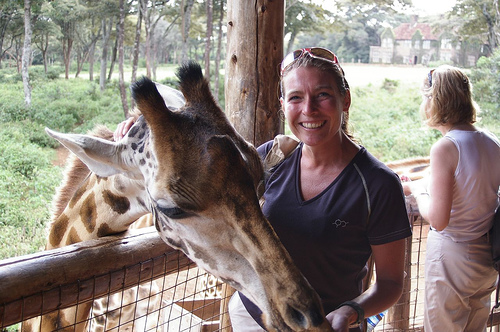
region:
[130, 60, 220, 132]
knobs on the head of a giraffe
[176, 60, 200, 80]
hair on the top of a knob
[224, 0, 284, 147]
a sturdy wooden post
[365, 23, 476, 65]
building in the distance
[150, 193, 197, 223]
right eye of a giraffe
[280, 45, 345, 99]
glasses on the head of a woman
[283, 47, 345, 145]
smiling face of a woman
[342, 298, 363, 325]
wrist watch on the arm of a woman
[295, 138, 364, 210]
V neck of a shirt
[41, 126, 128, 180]
left ear of the giraffe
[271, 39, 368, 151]
A woman's head with sunglasses on.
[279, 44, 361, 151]
A woman's head with small sunglasses on.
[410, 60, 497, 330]
A woman with a white shirt on.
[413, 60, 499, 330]
A woman with a white tanktop on.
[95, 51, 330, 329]
Head of a giraffe next to a woman.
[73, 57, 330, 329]
Big head of a giraffe next to a woman.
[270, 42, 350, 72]
Sunglasses on a woman's head.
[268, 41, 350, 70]
Red sunglasses on a woman's head.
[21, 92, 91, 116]
Bushes outside in the background.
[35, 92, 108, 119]
Green bushes outside in the background.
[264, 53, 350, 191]
the woman is smiling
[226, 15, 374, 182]
the woman is smiling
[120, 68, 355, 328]
giraffe feeding on woman's hand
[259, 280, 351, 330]
giraffe feeding on woman's hand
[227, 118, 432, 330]
giraffe feeding on woman's hand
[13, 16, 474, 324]
A giraffe in an enclosure.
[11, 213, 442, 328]
A wire fence.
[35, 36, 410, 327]
Woman petting a giraffe.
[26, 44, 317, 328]
Giraffe with head over a fence.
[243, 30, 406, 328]
Shirt with a v neckline.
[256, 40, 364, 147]
A pair of sunglasses.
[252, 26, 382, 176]
Woman has hair pulled back.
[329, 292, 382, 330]
Watch on woman's left wrist.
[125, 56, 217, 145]
Horns on giraffe's head.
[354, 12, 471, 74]
House in the background.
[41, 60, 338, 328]
the giraffe leaning over the fence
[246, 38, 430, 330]
the woman petting the giraffe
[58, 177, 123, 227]
the spots on the giraffe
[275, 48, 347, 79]
the sunglasses on the head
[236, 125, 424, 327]
the woman wearing a blue t shirt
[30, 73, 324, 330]
the head of the giraffe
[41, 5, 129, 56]
the trees with green leaves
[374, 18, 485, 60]
the house in the distance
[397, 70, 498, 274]
the woman wearing the white top